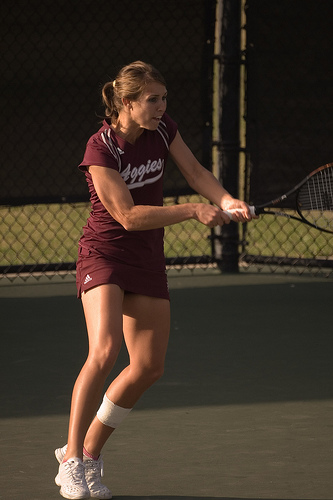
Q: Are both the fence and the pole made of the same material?
A: Yes, both the fence and the pole are made of metal.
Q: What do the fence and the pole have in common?
A: The material, both the fence and the pole are metallic.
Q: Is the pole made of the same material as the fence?
A: Yes, both the pole and the fence are made of metal.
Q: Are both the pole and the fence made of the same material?
A: Yes, both the pole and the fence are made of metal.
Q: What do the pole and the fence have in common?
A: The material, both the pole and the fence are metallic.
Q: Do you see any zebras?
A: No, there are no zebras.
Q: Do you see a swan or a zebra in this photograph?
A: No, there are no zebras or swans.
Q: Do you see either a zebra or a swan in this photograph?
A: No, there are no zebras or swans.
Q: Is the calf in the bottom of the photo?
A: Yes, the calf is in the bottom of the image.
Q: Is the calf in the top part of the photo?
A: No, the calf is in the bottom of the image.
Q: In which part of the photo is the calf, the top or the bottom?
A: The calf is in the bottom of the image.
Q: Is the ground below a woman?
A: Yes, the ground is below a woman.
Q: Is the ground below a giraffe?
A: No, the ground is below a woman.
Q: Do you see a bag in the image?
A: No, there are no bags.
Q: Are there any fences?
A: Yes, there is a fence.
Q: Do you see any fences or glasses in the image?
A: Yes, there is a fence.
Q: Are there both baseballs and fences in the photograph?
A: No, there is a fence but no baseballs.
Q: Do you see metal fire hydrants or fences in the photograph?
A: Yes, there is a metal fence.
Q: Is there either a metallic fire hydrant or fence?
A: Yes, there is a metal fence.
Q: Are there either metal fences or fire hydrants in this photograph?
A: Yes, there is a metal fence.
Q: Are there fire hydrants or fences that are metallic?
A: Yes, the fence is metallic.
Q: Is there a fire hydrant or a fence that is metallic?
A: Yes, the fence is metallic.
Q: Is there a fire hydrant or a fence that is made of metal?
A: Yes, the fence is made of metal.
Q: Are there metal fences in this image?
A: Yes, there is a metal fence.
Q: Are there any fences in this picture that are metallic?
A: Yes, there is a fence that is metallic.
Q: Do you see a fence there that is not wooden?
A: Yes, there is a metallic fence.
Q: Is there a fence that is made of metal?
A: Yes, there is a fence that is made of metal.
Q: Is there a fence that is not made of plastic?
A: Yes, there is a fence that is made of metal.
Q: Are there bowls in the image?
A: No, there are no bowls.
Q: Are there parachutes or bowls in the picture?
A: No, there are no bowls or parachutes.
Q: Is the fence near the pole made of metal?
A: Yes, the fence is made of metal.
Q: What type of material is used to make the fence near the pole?
A: The fence is made of metal.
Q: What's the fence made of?
A: The fence is made of metal.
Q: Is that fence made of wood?
A: No, the fence is made of metal.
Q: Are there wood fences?
A: No, there is a fence but it is made of metal.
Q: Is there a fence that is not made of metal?
A: No, there is a fence but it is made of metal.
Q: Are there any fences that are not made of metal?
A: No, there is a fence but it is made of metal.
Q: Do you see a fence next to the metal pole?
A: Yes, there is a fence next to the pole.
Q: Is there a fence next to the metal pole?
A: Yes, there is a fence next to the pole.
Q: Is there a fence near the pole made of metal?
A: Yes, there is a fence near the pole.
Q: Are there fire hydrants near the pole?
A: No, there is a fence near the pole.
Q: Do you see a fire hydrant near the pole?
A: No, there is a fence near the pole.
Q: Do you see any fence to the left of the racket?
A: Yes, there is a fence to the left of the racket.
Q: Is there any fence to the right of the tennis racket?
A: No, the fence is to the left of the tennis racket.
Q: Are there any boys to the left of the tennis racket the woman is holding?
A: No, there is a fence to the left of the racket.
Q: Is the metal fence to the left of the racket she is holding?
A: Yes, the fence is to the left of the tennis racket.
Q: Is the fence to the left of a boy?
A: No, the fence is to the left of the tennis racket.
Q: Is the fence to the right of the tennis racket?
A: No, the fence is to the left of the tennis racket.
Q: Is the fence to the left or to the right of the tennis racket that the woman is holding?
A: The fence is to the left of the racket.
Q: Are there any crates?
A: No, there are no crates.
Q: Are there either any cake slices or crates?
A: No, there are no crates or cake slices.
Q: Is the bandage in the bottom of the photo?
A: Yes, the bandage is in the bottom of the image.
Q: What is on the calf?
A: The bandage is on the calf.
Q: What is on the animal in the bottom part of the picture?
A: The bandage is on the calf.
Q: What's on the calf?
A: The bandage is on the calf.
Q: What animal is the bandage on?
A: The bandage is on the calf.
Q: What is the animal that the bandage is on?
A: The animal is a calf.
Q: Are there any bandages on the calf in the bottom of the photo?
A: Yes, there is a bandage on the calf.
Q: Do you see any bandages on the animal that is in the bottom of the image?
A: Yes, there is a bandage on the calf.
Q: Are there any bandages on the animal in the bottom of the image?
A: Yes, there is a bandage on the calf.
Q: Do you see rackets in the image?
A: Yes, there is a racket.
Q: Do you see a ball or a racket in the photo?
A: Yes, there is a racket.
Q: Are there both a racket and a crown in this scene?
A: No, there is a racket but no crowns.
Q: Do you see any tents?
A: No, there are no tents.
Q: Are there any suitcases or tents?
A: No, there are no tents or suitcases.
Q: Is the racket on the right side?
A: Yes, the racket is on the right of the image.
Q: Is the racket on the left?
A: No, the racket is on the right of the image.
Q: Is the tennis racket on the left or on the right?
A: The tennis racket is on the right of the image.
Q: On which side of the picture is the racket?
A: The racket is on the right of the image.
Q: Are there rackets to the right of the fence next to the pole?
A: Yes, there is a racket to the right of the fence.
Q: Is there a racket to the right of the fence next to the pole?
A: Yes, there is a racket to the right of the fence.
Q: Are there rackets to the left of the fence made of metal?
A: No, the racket is to the right of the fence.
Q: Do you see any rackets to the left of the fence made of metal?
A: No, the racket is to the right of the fence.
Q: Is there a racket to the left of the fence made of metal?
A: No, the racket is to the right of the fence.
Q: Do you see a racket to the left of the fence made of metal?
A: No, the racket is to the right of the fence.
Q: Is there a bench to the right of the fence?
A: No, there is a racket to the right of the fence.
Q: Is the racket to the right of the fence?
A: Yes, the racket is to the right of the fence.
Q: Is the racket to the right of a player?
A: No, the racket is to the right of the fence.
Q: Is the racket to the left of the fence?
A: No, the racket is to the right of the fence.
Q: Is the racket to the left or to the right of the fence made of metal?
A: The racket is to the right of the fence.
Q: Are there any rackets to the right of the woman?
A: Yes, there is a racket to the right of the woman.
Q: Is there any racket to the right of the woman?
A: Yes, there is a racket to the right of the woman.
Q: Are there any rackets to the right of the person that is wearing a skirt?
A: Yes, there is a racket to the right of the woman.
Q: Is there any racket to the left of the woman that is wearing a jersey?
A: No, the racket is to the right of the woman.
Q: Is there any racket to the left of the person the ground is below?
A: No, the racket is to the right of the woman.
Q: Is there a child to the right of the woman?
A: No, there is a racket to the right of the woman.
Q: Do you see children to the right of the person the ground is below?
A: No, there is a racket to the right of the woman.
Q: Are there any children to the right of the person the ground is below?
A: No, there is a racket to the right of the woman.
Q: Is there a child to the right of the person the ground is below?
A: No, there is a racket to the right of the woman.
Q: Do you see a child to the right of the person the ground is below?
A: No, there is a racket to the right of the woman.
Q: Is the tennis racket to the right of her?
A: Yes, the tennis racket is to the right of the woman.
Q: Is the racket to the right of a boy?
A: No, the racket is to the right of the woman.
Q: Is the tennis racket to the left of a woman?
A: No, the tennis racket is to the right of a woman.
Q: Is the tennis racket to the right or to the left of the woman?
A: The tennis racket is to the right of the woman.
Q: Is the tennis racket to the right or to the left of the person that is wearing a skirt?
A: The tennis racket is to the right of the woman.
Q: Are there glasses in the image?
A: No, there are no glasses.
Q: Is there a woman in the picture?
A: Yes, there is a woman.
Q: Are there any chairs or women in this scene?
A: Yes, there is a woman.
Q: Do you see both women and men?
A: No, there is a woman but no men.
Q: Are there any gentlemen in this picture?
A: No, there are no gentlemen.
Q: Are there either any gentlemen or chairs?
A: No, there are no gentlemen or chairs.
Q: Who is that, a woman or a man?
A: That is a woman.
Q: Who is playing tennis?
A: The woman is playing tennis.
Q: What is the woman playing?
A: The woman is playing tennis.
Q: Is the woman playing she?
A: Yes, the woman is playing tennis.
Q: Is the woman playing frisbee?
A: No, the woman is playing tennis.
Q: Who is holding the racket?
A: The woman is holding the racket.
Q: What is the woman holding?
A: The woman is holding the racket.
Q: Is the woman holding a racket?
A: Yes, the woman is holding a racket.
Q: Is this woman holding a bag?
A: No, the woman is holding a racket.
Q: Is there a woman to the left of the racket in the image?
A: Yes, there is a woman to the left of the racket.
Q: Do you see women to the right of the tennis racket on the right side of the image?
A: No, the woman is to the left of the racket.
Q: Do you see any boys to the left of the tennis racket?
A: No, there is a woman to the left of the tennis racket.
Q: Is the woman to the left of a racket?
A: Yes, the woman is to the left of a racket.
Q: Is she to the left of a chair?
A: No, the woman is to the left of a racket.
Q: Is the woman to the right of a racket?
A: No, the woman is to the left of a racket.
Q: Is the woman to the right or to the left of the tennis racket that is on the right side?
A: The woman is to the left of the tennis racket.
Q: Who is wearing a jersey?
A: The woman is wearing a jersey.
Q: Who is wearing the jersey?
A: The woman is wearing a jersey.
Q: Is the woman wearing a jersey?
A: Yes, the woman is wearing a jersey.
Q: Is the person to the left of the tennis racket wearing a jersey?
A: Yes, the woman is wearing a jersey.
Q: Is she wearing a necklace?
A: No, the woman is wearing a jersey.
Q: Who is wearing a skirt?
A: The woman is wearing a skirt.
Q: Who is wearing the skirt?
A: The woman is wearing a skirt.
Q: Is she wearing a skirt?
A: Yes, the woman is wearing a skirt.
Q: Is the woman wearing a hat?
A: No, the woman is wearing a skirt.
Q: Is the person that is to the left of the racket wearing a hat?
A: No, the woman is wearing a skirt.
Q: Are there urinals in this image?
A: No, there are no urinals.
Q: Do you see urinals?
A: No, there are no urinals.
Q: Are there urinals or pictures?
A: No, there are no urinals or pictures.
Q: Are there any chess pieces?
A: No, there are no chess pieces.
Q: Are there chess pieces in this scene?
A: No, there are no chess pieces.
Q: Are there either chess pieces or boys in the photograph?
A: No, there are no chess pieces or boys.